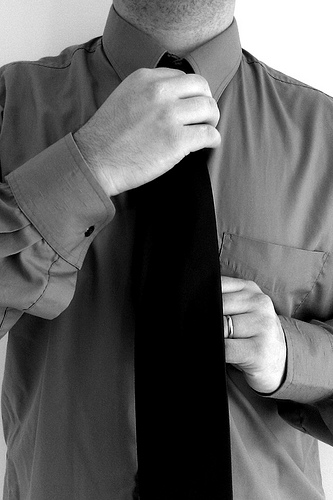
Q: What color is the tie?
A: Black.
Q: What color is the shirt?
A: Gray.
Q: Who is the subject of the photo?
A: The man.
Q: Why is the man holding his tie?
A: To tighten it.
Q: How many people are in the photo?
A: One.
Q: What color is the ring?
A: Silver.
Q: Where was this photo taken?
A: In a photography studio.